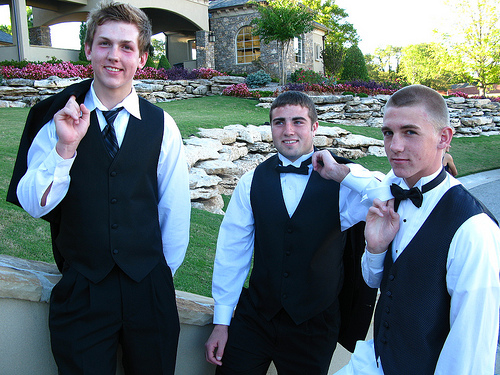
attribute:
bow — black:
[385, 176, 446, 211]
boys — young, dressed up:
[1, 2, 498, 374]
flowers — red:
[352, 80, 479, 105]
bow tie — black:
[385, 167, 454, 204]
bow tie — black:
[385, 179, 423, 211]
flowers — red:
[273, 76, 452, 97]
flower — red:
[222, 82, 233, 93]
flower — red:
[147, 67, 157, 76]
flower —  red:
[312, 82, 321, 88]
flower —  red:
[342, 82, 353, 92]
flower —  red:
[53, 64, 60, 73]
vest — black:
[221, 63, 376, 370]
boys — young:
[203, 83, 498, 373]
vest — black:
[373, 183, 499, 373]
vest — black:
[248, 152, 343, 334]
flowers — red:
[162, 58, 222, 80]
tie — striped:
[92, 107, 122, 143]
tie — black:
[374, 166, 459, 208]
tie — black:
[263, 155, 317, 180]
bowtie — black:
[264, 150, 315, 185]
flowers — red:
[2, 63, 262, 103]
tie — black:
[275, 152, 338, 185]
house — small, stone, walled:
[208, 0, 335, 83]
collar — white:
[84, 87, 144, 120]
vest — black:
[49, 97, 166, 284]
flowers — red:
[220, 79, 253, 96]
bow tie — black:
[250, 157, 318, 182]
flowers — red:
[202, 84, 258, 105]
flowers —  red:
[221, 73, 251, 102]